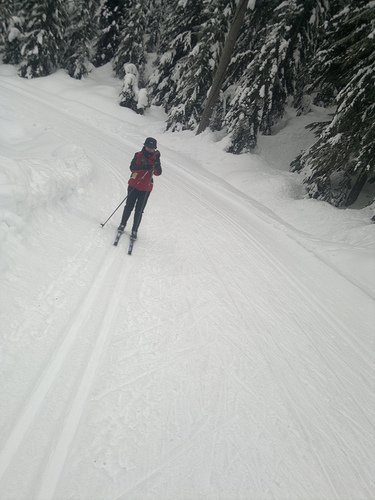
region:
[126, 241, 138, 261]
ski on person's foot.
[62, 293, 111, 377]
ski path in the snow.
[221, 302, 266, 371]
ski tracks on the path.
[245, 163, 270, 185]
snow on the ground.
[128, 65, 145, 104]
snow on the tree.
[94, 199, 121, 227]
ski pole in woman's hand.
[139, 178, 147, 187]
red coat on skier.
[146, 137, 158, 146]
hat on skier's head.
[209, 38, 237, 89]
trunk of tree.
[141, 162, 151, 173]
glove on skier's hand.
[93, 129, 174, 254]
A person sking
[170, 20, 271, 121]
Heavy snow on the trees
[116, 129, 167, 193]
Skier has a red jacket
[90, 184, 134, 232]
The skier is hilding a ski pole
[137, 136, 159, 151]
A black hat on head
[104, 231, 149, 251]
skis on feet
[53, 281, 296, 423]
Snow on the slop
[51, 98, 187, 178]
Trail for skiers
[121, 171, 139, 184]
Yellow pocket on skier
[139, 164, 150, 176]
Mittens on skier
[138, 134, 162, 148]
she is wearing a hat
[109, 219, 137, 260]
she is wearing skiies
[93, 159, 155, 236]
she is holding her ski pole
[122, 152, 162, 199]
She is wearing a red jacket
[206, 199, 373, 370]
ski tracks in the snow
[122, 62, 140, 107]
snow covers the branch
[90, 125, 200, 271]
she is skiing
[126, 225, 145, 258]
her skies are blue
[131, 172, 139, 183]
her pocket is yellow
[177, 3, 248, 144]
a pole at the side of the trail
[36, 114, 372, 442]
a well groomed ski trail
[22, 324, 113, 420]
ski marks on a snowy ski trail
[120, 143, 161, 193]
a red and grey ski jacket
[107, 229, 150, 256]
a pair of black skis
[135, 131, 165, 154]
a black hat with a visor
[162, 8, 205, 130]
pine trees covered in white fluffy snow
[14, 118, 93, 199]
an ungroomed side bank of a ski trail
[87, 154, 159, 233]
black metal ski poles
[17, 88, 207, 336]
a woman skiing down a trail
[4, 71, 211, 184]
a curved ski trail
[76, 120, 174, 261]
This is a woman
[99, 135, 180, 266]
Leg of a lady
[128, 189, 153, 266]
Leg of a woman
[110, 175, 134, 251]
Leg of a woman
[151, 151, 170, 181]
Hand of a woman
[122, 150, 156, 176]
Hand of a woman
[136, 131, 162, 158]
Head of a woman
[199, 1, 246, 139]
This is a tree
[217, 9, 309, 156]
This is a tree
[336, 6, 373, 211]
This is a tree